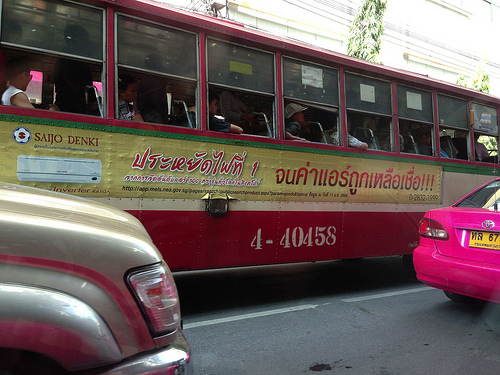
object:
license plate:
[469, 231, 500, 251]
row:
[1, 1, 500, 166]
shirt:
[1, 84, 29, 106]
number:
[251, 229, 263, 250]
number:
[280, 228, 291, 249]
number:
[303, 227, 314, 247]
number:
[315, 227, 326, 246]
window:
[0, 0, 111, 116]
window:
[113, 11, 201, 129]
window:
[205, 36, 279, 138]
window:
[281, 55, 344, 147]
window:
[342, 70, 392, 150]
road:
[174, 256, 499, 374]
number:
[292, 227, 304, 247]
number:
[326, 226, 337, 245]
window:
[163, 30, 370, 151]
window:
[163, 35, 319, 153]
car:
[412, 177, 500, 305]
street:
[174, 254, 499, 374]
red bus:
[0, 0, 499, 276]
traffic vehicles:
[0, 0, 499, 276]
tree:
[350, 2, 389, 62]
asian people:
[118, 77, 144, 122]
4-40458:
[251, 226, 337, 250]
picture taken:
[1, 2, 500, 375]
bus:
[0, 0, 500, 279]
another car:
[0, 180, 193, 374]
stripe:
[123, 174, 263, 187]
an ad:
[0, 112, 441, 203]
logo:
[17, 155, 103, 184]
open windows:
[0, 0, 104, 118]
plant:
[346, 0, 385, 65]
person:
[0, 61, 35, 108]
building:
[171, 0, 500, 99]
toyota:
[412, 176, 499, 304]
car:
[0, 182, 191, 375]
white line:
[183, 286, 437, 329]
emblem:
[481, 220, 495, 229]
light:
[418, 217, 450, 241]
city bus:
[0, 0, 500, 273]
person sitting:
[118, 77, 145, 121]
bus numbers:
[251, 226, 337, 250]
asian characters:
[122, 146, 261, 187]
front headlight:
[126, 261, 181, 337]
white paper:
[301, 64, 323, 89]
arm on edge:
[224, 115, 253, 138]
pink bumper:
[413, 247, 500, 304]